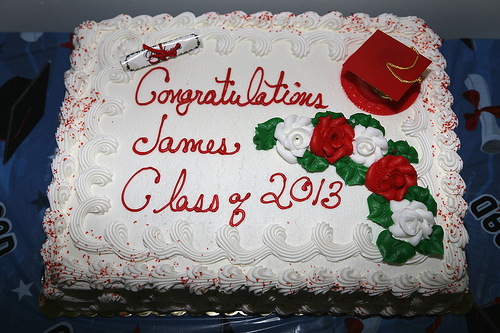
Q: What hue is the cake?
A: White.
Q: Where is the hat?
A: On cake.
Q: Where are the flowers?
A: On cake.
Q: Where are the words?
A: On cake.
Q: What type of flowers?
A: Roses.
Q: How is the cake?
A: Frosted.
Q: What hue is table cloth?
A: Blue.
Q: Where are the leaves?
A: On cake.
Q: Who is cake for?
A: James.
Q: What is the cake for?
A: Celebration.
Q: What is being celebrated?
A: Graduation.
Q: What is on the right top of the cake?
A: A graduation cap.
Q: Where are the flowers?
A: ON the cake.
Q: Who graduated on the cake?
A: James.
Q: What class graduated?
A: 2013.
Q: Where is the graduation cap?
A: On the cake.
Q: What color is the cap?
A: Red.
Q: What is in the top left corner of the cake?
A: A diploma.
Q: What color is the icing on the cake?
A: White.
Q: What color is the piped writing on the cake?
A: Red.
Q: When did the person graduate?
A: 2013.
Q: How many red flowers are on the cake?
A: Two.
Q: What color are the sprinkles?
A: Red.